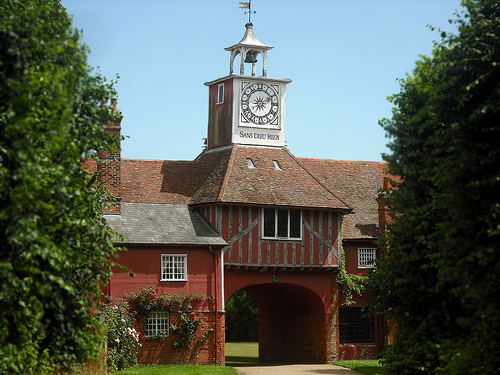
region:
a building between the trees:
[78, 0, 433, 374]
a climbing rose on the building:
[114, 286, 226, 369]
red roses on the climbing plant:
[126, 284, 206, 338]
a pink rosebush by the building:
[96, 306, 144, 368]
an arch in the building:
[214, 281, 340, 370]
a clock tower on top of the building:
[197, 1, 289, 149]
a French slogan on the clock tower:
[223, 127, 285, 146]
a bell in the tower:
[234, 44, 268, 78]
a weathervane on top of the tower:
[237, 0, 259, 27]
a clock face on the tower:
[235, 81, 283, 127]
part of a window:
[162, 245, 204, 321]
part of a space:
[255, 308, 291, 367]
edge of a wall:
[216, 335, 231, 359]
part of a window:
[271, 195, 306, 255]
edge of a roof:
[178, 225, 194, 242]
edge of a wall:
[219, 326, 229, 341]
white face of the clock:
[242, 83, 280, 125]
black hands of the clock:
[256, 94, 269, 115]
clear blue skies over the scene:
[309, 30, 368, 141]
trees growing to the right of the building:
[374, 33, 499, 337]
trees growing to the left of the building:
[0, 77, 114, 344]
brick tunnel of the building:
[224, 284, 329, 370]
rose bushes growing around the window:
[103, 290, 215, 357]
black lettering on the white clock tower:
[239, 130, 285, 150]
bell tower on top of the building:
[224, 16, 269, 75]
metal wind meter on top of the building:
[231, 0, 256, 29]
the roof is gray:
[144, 214, 179, 239]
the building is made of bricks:
[283, 323, 310, 340]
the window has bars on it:
[156, 248, 193, 285]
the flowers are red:
[134, 286, 165, 305]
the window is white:
[153, 251, 196, 282]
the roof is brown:
[144, 165, 168, 190]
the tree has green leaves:
[424, 157, 454, 219]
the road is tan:
[281, 364, 297, 374]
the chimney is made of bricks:
[103, 157, 120, 184]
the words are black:
[235, 127, 282, 144]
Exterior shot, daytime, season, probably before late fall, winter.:
[5, 2, 492, 372]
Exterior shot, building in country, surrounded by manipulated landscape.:
[1, 0, 497, 366]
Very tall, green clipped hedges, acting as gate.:
[7, 2, 497, 364]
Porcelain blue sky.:
[130, 8, 171, 93]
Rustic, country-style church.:
[98, 0, 478, 371]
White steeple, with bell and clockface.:
[210, 10, 293, 147]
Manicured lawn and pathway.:
[150, 345, 391, 371]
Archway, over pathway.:
[221, 268, 344, 373]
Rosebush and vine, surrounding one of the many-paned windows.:
[110, 262, 210, 363]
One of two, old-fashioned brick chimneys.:
[79, 93, 124, 217]